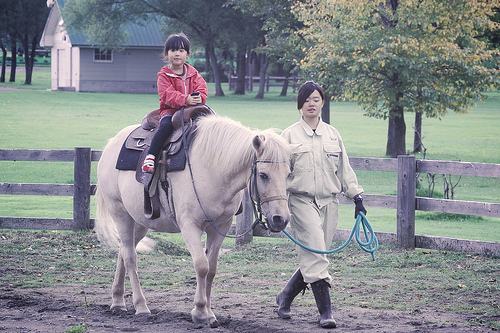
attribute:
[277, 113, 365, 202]
shirt — white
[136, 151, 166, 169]
shoes — red , white 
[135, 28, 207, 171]
girl — little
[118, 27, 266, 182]
asian girl — small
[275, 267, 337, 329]
boots — black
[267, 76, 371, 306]
woman — asian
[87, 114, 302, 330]
horse — black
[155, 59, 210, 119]
jacket — red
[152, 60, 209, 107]
jacket — red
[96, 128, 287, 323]
horse — white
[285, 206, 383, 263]
lead — green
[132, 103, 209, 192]
saddle — brown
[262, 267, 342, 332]
boots — black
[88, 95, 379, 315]
horse — tan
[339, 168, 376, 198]
gloves — black 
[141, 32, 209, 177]
girl — small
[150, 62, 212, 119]
jacket — red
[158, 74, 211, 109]
rain jacket — red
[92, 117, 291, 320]
horse — white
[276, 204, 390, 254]
leash — green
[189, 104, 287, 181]
hair — blonde 